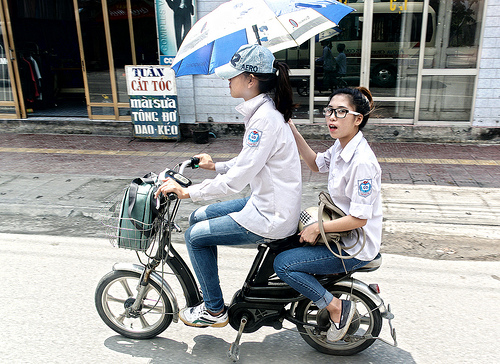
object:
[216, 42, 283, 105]
person's head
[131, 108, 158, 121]
letter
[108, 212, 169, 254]
basket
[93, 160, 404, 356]
scooter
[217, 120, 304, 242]
shirt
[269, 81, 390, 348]
people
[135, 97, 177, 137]
letter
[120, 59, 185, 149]
sign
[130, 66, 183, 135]
sign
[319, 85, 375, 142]
head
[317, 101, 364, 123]
glasses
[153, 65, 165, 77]
letter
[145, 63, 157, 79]
letter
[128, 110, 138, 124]
letter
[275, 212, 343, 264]
hand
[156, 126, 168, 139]
letter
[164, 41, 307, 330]
person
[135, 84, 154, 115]
letter